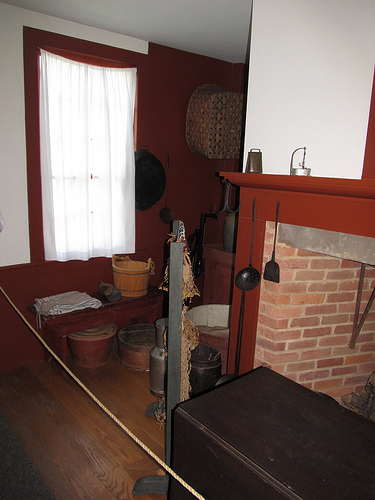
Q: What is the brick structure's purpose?
A: Making a fire.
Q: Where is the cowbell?
A: Mantle.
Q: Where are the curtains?
A: On the wall.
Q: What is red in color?
A: Wall.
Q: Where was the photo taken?
A: In a room.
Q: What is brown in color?
A: Ground.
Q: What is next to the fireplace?
A: Chest.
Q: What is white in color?
A: Curtains.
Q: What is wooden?
A: The bench.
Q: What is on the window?
A: Curtain.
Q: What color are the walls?
A: Red.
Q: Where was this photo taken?
A: In a person's home.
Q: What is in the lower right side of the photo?
A: A fire place.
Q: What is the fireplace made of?
A: Bricks.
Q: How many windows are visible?
A: One.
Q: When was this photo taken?
A: Inside, during the daytime.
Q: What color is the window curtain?
A: White.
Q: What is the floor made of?
A: Wood.